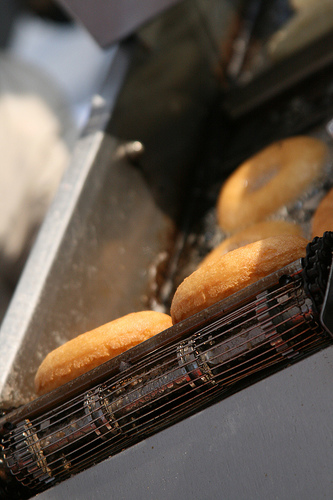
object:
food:
[31, 311, 174, 395]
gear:
[0, 263, 333, 500]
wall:
[21, 347, 332, 500]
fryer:
[0, 122, 332, 499]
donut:
[169, 234, 313, 325]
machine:
[0, 0, 333, 500]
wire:
[0, 263, 318, 500]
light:
[0, 94, 333, 500]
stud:
[112, 136, 143, 159]